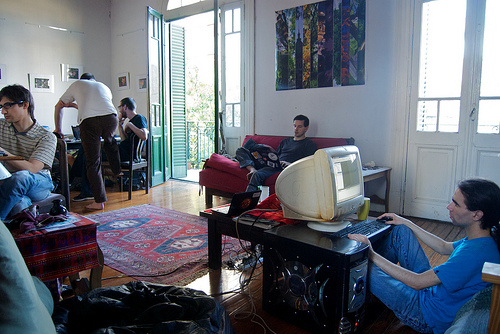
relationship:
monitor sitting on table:
[273, 143, 367, 223] [205, 202, 397, 332]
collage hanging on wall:
[271, 0, 367, 92] [254, 5, 394, 209]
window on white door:
[473, 0, 499, 134] [468, 2, 499, 187]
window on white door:
[415, 0, 467, 132] [400, 0, 478, 226]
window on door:
[147, 32, 161, 105] [144, 5, 166, 185]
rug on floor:
[88, 202, 253, 289] [55, 177, 498, 332]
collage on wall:
[271, 0, 367, 92] [254, 5, 394, 209]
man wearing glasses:
[0, 83, 60, 247] [0, 100, 16, 115]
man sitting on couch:
[235, 114, 321, 222] [196, 131, 326, 211]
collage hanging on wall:
[271, 0, 367, 92] [1, 2, 497, 224]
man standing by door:
[51, 66, 122, 206] [154, 6, 247, 168]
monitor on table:
[273, 143, 367, 234] [198, 195, 392, 297]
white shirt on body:
[61, 79, 117, 123] [59, 81, 139, 191]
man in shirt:
[4, 80, 76, 247] [2, 118, 62, 175]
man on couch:
[238, 93, 351, 222] [193, 125, 382, 221]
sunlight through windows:
[423, 46, 453, 91] [411, 2, 491, 139]